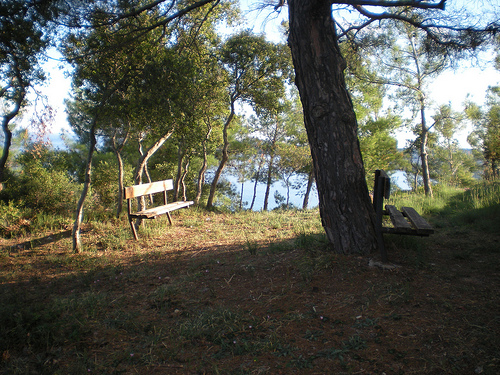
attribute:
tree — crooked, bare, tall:
[279, 12, 373, 260]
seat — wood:
[109, 163, 191, 270]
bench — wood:
[124, 173, 187, 229]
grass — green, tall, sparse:
[397, 175, 489, 246]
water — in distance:
[214, 173, 320, 206]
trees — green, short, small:
[81, 26, 296, 178]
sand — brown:
[166, 210, 286, 235]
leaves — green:
[76, 33, 284, 176]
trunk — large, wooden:
[302, 37, 376, 243]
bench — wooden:
[368, 170, 428, 251]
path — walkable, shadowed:
[185, 231, 379, 343]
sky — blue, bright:
[27, 57, 78, 150]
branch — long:
[341, 1, 456, 51]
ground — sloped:
[102, 175, 462, 342]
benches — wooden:
[91, 162, 460, 238]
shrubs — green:
[15, 141, 122, 226]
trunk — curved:
[70, 126, 169, 262]